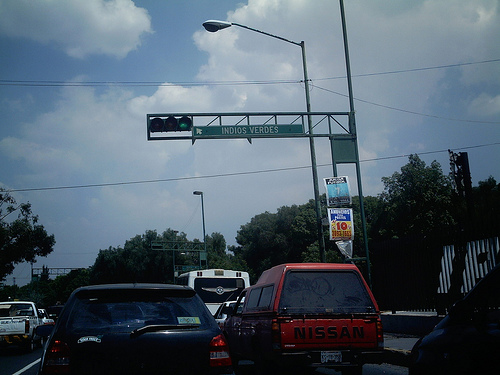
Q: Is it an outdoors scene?
A: Yes, it is outdoors.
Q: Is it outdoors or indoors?
A: It is outdoors.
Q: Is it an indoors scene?
A: No, it is outdoors.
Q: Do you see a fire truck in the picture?
A: No, there are no fire trucks.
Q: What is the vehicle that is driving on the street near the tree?
A: The vehicle is a car.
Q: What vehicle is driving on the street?
A: The vehicle is a car.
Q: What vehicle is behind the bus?
A: The vehicle is a car.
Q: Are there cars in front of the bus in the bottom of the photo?
A: No, the car is behind the bus.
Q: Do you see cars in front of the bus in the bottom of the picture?
A: No, the car is behind the bus.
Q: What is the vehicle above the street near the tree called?
A: The vehicle is a car.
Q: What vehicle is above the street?
A: The vehicle is a car.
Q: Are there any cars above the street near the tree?
A: Yes, there is a car above the street.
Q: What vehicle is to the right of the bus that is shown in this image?
A: The vehicle is a car.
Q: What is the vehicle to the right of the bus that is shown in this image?
A: The vehicle is a car.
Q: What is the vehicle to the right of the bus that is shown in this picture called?
A: The vehicle is a car.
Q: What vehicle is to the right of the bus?
A: The vehicle is a car.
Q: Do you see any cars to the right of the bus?
A: Yes, there is a car to the right of the bus.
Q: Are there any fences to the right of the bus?
A: No, there is a car to the right of the bus.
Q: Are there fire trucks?
A: No, there are no fire trucks.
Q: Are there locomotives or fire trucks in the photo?
A: No, there are no fire trucks or locomotives.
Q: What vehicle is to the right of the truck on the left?
A: The vehicle is a car.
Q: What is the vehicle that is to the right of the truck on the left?
A: The vehicle is a car.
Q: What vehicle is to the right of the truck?
A: The vehicle is a car.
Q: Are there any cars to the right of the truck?
A: Yes, there is a car to the right of the truck.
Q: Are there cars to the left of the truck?
A: No, the car is to the right of the truck.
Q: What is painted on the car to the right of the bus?
A: The logo is painted on the car.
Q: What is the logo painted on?
A: The logo is painted on the car.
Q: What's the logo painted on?
A: The logo is painted on the car.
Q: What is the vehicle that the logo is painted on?
A: The vehicle is a car.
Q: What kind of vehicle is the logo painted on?
A: The logo is painted on the car.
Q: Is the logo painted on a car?
A: Yes, the logo is painted on a car.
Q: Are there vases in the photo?
A: No, there are no vases.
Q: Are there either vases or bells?
A: No, there are no vases or bells.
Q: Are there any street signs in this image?
A: Yes, there is a street sign.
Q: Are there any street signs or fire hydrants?
A: Yes, there is a street sign.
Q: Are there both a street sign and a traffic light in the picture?
A: Yes, there are both a street sign and a traffic light.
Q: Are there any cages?
A: No, there are no cages.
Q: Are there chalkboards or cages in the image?
A: No, there are no cages or chalkboards.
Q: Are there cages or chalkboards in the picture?
A: No, there are no cages or chalkboards.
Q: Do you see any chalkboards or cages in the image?
A: No, there are no cages or chalkboards.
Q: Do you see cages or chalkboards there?
A: No, there are no cages or chalkboards.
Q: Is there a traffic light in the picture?
A: Yes, there is a traffic light.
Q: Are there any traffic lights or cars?
A: Yes, there is a traffic light.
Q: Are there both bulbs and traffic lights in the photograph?
A: No, there is a traffic light but no light bulbs.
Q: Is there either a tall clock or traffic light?
A: Yes, there is a tall traffic light.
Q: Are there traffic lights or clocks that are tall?
A: Yes, the traffic light is tall.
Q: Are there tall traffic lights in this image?
A: Yes, there is a tall traffic light.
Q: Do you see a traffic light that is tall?
A: Yes, there is a traffic light that is tall.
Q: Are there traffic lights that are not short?
A: Yes, there is a tall traffic light.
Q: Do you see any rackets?
A: No, there are no rackets.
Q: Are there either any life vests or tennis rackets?
A: No, there are no tennis rackets or life vests.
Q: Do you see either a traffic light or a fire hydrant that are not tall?
A: No, there is a traffic light but it is tall.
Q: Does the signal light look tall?
A: Yes, the signal light is tall.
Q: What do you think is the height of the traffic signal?
A: The traffic signal is tall.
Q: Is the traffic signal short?
A: No, the traffic signal is tall.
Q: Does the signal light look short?
A: No, the signal light is tall.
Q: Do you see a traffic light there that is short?
A: No, there is a traffic light but it is tall.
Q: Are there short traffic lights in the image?
A: No, there is a traffic light but it is tall.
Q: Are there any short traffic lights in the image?
A: No, there is a traffic light but it is tall.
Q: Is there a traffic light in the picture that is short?
A: No, there is a traffic light but it is tall.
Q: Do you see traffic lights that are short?
A: No, there is a traffic light but it is tall.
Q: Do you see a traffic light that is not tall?
A: No, there is a traffic light but it is tall.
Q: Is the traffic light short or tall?
A: The traffic light is tall.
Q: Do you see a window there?
A: Yes, there is a window.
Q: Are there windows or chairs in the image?
A: Yes, there is a window.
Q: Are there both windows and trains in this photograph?
A: No, there is a window but no trains.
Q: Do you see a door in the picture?
A: No, there are no doors.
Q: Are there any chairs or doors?
A: No, there are no doors or chairs.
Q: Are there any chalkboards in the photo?
A: No, there are no chalkboards.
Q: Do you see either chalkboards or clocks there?
A: No, there are no chalkboards or clocks.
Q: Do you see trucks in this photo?
A: Yes, there is a truck.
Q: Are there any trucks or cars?
A: Yes, there is a truck.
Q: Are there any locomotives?
A: No, there are no locomotives.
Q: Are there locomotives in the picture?
A: No, there are no locomotives.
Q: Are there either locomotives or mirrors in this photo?
A: No, there are no locomotives or mirrors.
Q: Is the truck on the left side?
A: Yes, the truck is on the left of the image.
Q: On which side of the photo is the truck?
A: The truck is on the left of the image.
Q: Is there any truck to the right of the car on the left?
A: No, the truck is to the left of the car.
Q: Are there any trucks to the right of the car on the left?
A: No, the truck is to the left of the car.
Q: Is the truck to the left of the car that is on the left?
A: Yes, the truck is to the left of the car.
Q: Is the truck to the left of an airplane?
A: No, the truck is to the left of the car.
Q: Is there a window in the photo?
A: Yes, there is a window.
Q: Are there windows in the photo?
A: Yes, there is a window.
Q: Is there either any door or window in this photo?
A: Yes, there is a window.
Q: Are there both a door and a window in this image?
A: No, there is a window but no doors.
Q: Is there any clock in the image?
A: No, there are no clocks.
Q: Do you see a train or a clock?
A: No, there are no clocks or trains.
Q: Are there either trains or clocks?
A: No, there are no clocks or trains.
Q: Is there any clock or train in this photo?
A: No, there are no clocks or trains.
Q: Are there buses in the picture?
A: Yes, there is a bus.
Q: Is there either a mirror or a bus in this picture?
A: Yes, there is a bus.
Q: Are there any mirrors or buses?
A: Yes, there is a bus.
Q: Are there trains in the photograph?
A: No, there are no trains.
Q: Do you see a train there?
A: No, there are no trains.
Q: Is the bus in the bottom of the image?
A: Yes, the bus is in the bottom of the image.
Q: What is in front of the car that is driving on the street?
A: The bus is in front of the car.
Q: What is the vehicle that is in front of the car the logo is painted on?
A: The vehicle is a bus.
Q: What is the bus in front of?
A: The bus is in front of the car.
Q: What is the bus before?
A: The bus is in front of the car.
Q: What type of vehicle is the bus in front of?
A: The bus is in front of the car.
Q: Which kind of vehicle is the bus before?
A: The bus is in front of the car.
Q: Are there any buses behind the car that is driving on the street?
A: No, the bus is in front of the car.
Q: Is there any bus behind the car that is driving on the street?
A: No, the bus is in front of the car.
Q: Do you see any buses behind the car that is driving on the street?
A: No, the bus is in front of the car.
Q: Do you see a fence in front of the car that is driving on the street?
A: No, there is a bus in front of the car.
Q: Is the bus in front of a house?
A: No, the bus is in front of a car.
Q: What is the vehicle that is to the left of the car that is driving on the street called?
A: The vehicle is a bus.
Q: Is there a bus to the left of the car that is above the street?
A: Yes, there is a bus to the left of the car.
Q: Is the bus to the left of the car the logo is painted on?
A: Yes, the bus is to the left of the car.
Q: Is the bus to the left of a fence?
A: No, the bus is to the left of the car.